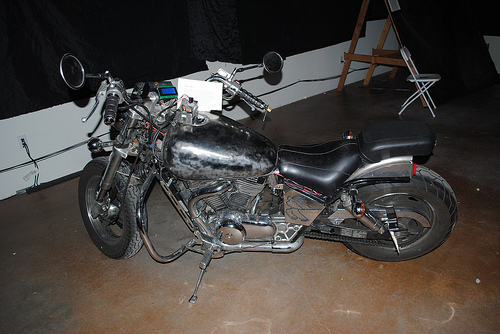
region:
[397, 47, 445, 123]
a white folding chair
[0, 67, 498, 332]
a dirty brown floor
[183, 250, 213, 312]
the kickstand on a motorcycle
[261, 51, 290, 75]
a side mirror on a motorcycle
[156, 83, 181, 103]
a green cellphone on a motorcycle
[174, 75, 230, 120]
a white paper propped on a motorcycle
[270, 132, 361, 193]
a padded black seat on a motorcycle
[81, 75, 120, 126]
the handlebar of a motorcycle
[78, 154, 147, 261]
the black front wheel of a motorcycle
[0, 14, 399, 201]
a white wall in a room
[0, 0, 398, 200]
a white wall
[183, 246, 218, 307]
a kickstand on a motorcycle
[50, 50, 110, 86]
a side mirror on a motorcycle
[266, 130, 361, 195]
the black padded seat on a motorcycle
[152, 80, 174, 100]
a green cellphone on a motorcycle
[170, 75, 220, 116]
a white paper on a motorcycle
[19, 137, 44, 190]
a cord plugged into a wall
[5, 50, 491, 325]
brown floor with grey coating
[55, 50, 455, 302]
motorcycle parked on floor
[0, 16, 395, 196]
long white panel across floor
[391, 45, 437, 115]
small white folding chair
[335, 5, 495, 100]
wooden supports for slanted wood surface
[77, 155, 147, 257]
dust on edge of tire treads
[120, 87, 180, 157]
jumble of wires, metal pieces and connectors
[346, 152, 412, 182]
twisted black tire panel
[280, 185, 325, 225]
brown panel of face with arms to side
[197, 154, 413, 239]
A parked motorcycle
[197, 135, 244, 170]
Metallic fuel tank cover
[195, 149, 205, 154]
Reflection on the cover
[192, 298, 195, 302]
The prop for the motorcycle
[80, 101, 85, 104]
Shadow cast by the side mirror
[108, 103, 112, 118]
The motorcycle handle bar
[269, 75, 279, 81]
Shadow cast on the wood by a mirror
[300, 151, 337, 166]
The rider's seat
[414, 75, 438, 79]
A seat on the floor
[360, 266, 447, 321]
The surface of the floor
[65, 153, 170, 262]
the wheel on a bike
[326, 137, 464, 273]
the back wheel on a bike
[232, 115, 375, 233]
the seat on a bike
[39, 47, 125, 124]
the mirror on a bike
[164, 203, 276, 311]
the kick stand on a bike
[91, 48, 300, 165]
the handlebars on a bike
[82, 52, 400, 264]
a bike in a room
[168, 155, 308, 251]
the engine on a bike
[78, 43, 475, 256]
a little black bike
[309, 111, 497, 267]
the back of a bike